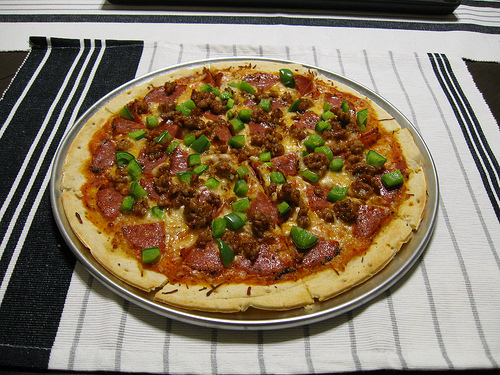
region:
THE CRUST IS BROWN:
[281, 300, 296, 308]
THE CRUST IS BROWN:
[263, 292, 281, 314]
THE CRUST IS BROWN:
[269, 293, 282, 310]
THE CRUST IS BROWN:
[267, 301, 276, 305]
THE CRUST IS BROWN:
[276, 301, 285, 306]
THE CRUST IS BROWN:
[257, 293, 272, 305]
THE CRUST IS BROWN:
[253, 286, 272, 319]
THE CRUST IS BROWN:
[259, 303, 270, 308]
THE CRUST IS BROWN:
[264, 302, 283, 317]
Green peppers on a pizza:
[286, 217, 317, 252]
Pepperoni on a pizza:
[117, 218, 168, 249]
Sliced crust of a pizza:
[152, 273, 318, 311]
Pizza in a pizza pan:
[50, 65, 430, 322]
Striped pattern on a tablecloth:
[39, 327, 318, 374]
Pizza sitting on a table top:
[47, 48, 452, 336]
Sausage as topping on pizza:
[302, 150, 334, 178]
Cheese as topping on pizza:
[164, 210, 189, 255]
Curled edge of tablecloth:
[19, 30, 195, 57]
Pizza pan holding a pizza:
[417, 142, 439, 268]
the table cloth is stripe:
[379, 337, 413, 352]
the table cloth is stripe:
[385, 343, 406, 360]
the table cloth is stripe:
[391, 345, 410, 354]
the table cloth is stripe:
[389, 332, 415, 367]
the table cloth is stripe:
[397, 335, 410, 357]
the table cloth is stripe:
[399, 340, 409, 350]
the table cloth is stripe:
[397, 345, 407, 359]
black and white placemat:
[6, 31, 498, 370]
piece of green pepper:
[262, 166, 289, 185]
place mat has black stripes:
[52, 51, 454, 373]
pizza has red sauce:
[96, 151, 268, 306]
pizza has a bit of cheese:
[266, 156, 385, 308]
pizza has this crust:
[166, 238, 321, 318]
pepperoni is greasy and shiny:
[237, 223, 377, 273]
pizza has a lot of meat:
[48, 46, 482, 323]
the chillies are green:
[289, 231, 303, 245]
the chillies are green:
[297, 226, 307, 242]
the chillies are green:
[304, 221, 306, 243]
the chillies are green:
[284, 228, 306, 249]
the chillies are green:
[284, 236, 306, 246]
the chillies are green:
[294, 218, 304, 248]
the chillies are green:
[293, 234, 308, 246]